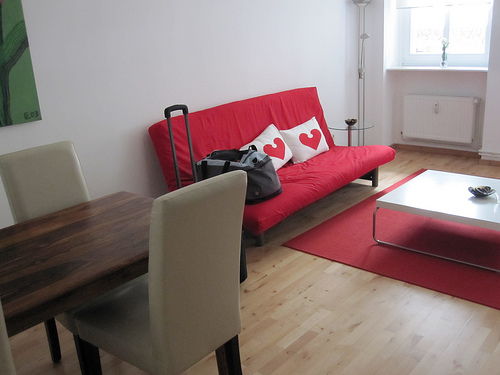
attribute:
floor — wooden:
[148, 139, 497, 374]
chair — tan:
[93, 212, 265, 370]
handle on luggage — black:
[166, 105, 199, 186]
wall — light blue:
[6, 4, 355, 132]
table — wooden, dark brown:
[4, 198, 231, 319]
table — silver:
[373, 172, 498, 249]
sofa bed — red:
[162, 92, 404, 215]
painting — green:
[2, 2, 43, 130]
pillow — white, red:
[287, 121, 329, 152]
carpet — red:
[281, 167, 499, 311]